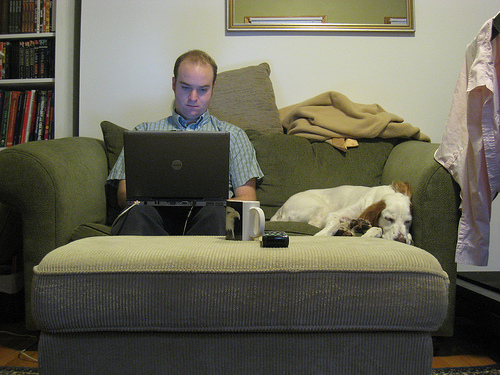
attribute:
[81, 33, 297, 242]
man — sitting, otto, looking, using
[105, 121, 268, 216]
laptop — gray, computer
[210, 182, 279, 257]
cup — coffee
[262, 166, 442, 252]
dog — sleeping, white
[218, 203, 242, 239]
ottoman — gray, green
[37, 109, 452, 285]
couch — green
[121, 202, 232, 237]
pant — gray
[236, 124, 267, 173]
shirt — plaid, wrinkled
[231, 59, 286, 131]
pillow — throw, brown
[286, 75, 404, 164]
blanket — brown, crumpled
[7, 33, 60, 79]
books — full, filled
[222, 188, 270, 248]
mug — coffee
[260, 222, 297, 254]
remote — tv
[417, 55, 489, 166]
coat — pink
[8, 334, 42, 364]
floor — hardwood